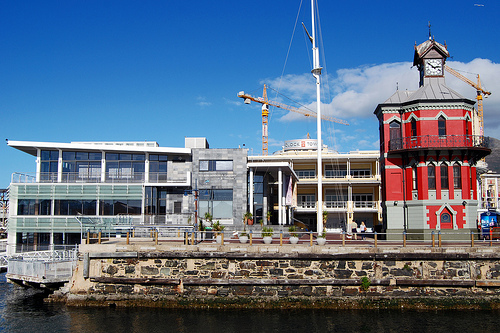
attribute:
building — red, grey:
[374, 20, 494, 244]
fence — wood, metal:
[85, 228, 499, 246]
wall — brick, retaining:
[143, 235, 313, 315]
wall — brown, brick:
[65, 244, 499, 311]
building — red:
[381, 25, 491, 233]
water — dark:
[12, 304, 474, 328]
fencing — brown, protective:
[84, 225, 499, 250]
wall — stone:
[3, 250, 470, 293]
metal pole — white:
[299, 94, 345, 211]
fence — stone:
[160, 217, 452, 252]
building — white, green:
[6, 127, 214, 267]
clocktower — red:
[373, 35, 490, 245]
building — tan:
[251, 149, 381, 233]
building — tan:
[368, 20, 481, 245]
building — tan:
[5, 129, 249, 244]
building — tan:
[478, 163, 499, 215]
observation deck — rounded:
[385, 132, 494, 166]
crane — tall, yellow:
[238, 82, 352, 154]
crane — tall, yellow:
[234, 80, 290, 155]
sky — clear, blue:
[1, 2, 498, 185]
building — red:
[375, 37, 492, 252]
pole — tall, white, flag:
[304, 2, 329, 245]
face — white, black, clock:
[426, 58, 441, 75]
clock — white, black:
[415, 36, 447, 81]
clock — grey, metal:
[427, 37, 476, 79]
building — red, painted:
[377, 31, 481, 234]